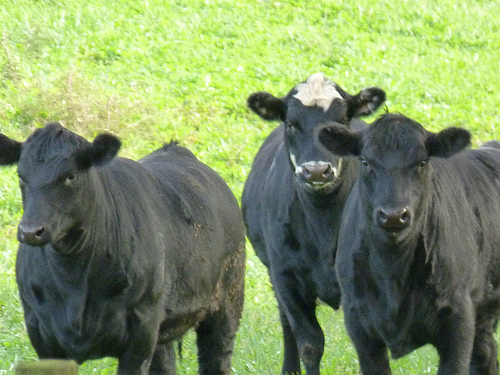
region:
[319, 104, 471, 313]
A black cow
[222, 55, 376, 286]
A black and white cow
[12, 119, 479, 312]
two black cows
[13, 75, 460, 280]
A black and white cow between two black cows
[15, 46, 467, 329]
three cows in green grass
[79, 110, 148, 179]
the left ear of a cow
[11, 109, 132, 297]
the head of a cow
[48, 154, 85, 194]
the left eye of a cow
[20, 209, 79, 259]
the nose of a cow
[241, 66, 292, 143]
the right ear of a cow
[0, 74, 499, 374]
Cows in the field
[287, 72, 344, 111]
White patch of hair on cow.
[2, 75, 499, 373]
Cows looking at camera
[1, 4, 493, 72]
Grass in a field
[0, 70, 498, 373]
Cows standing still answer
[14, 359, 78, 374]
A wooden post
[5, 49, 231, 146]
A patch of brown grass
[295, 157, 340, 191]
Open mouth of a cow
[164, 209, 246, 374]
Dirt on cow fur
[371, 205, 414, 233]
A shiny cow nose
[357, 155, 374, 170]
the eye of a cow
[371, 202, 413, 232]
the nose of a cow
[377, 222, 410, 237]
the mouth of a cow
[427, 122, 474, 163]
the ear of a cow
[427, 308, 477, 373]
the leg of a cow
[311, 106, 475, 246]
the head of a cow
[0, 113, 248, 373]
a black cow on the grass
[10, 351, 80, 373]
a wooden fence post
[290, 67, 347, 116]
a white spot on the cow's head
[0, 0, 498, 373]
a green grassy field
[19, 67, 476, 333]
three black cows facing forward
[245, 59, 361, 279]
black cow with white spot on top of head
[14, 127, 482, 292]
two solid black cows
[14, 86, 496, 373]
cows standing in green grass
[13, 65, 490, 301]
three large cows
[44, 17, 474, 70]
short green grass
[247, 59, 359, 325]
cow with white markings around mouth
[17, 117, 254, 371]
cow with dirt around hind quarters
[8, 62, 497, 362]
three farm animals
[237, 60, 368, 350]
cow standing between two cows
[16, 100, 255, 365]
The black cow closest to the left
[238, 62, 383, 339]
the black cow in the middle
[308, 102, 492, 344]
the black cow on the right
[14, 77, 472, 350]
a group of 3 cows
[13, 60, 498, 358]
a group of 3 black cows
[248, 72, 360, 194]
The only cow with a white spot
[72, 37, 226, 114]
some grass in the background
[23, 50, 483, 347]
a group of cows making mean faces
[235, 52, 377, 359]
the tallest of the three cows according to the picture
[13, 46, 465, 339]
3 female black cows